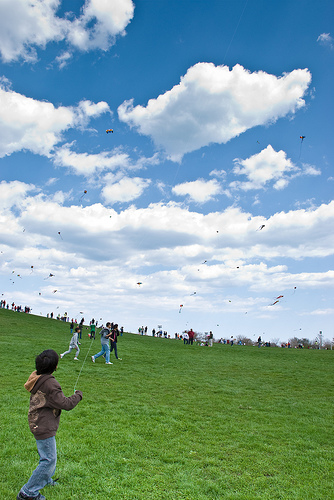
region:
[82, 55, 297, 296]
big white cloud formations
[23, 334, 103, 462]
a boy in a sweatshirt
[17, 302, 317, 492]
a large grass covered lawn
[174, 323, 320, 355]
a few distant trees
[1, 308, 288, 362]
a large group of people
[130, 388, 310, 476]
some short cut grass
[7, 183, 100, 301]
a bunch of kites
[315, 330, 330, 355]
a distant tower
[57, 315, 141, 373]
a family walking on gras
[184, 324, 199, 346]
a man wearing red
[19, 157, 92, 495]
boy with a kite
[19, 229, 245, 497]
boy with a kite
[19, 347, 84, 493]
a boy standing in field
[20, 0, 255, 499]
a boy flying a kite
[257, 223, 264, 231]
a kite in flight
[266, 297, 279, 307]
a kite in flight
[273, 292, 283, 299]
a kite in flight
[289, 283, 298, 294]
a kite in flight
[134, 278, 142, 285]
a kite in flight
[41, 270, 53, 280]
a kite in flight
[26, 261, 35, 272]
a kite in flight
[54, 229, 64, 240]
a kite in flight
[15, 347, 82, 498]
A boy in a brown sweatshirt flying a kite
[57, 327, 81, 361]
A child in gray running behind tw people.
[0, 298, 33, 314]
Group of people on the top of the sloping hill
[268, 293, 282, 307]
Two long kites toward the bottom right sky.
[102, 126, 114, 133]
Highest largest kite in the sky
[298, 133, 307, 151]
Kite flying highest to the right.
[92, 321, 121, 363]
Two people walking in front a child who is running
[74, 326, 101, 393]
White string a boy in a brown sweatshirt is holding onto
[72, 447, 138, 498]
Green grass in front of a boy in brown.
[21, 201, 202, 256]
Large puffy white cloud mostly on the left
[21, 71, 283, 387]
the sky is white and blue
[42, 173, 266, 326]
the sky is white and blue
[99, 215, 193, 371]
the sky is white and blue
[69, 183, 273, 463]
the sky is white and blue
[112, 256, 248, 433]
the sky is white and blue